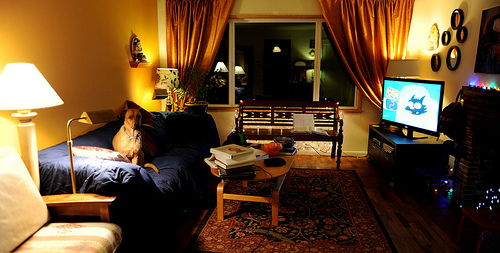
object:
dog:
[112, 108, 161, 173]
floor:
[29, 120, 289, 154]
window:
[195, 19, 360, 107]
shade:
[0, 62, 61, 109]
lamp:
[0, 63, 66, 193]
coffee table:
[208, 133, 299, 225]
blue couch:
[37, 110, 222, 248]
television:
[378, 77, 443, 138]